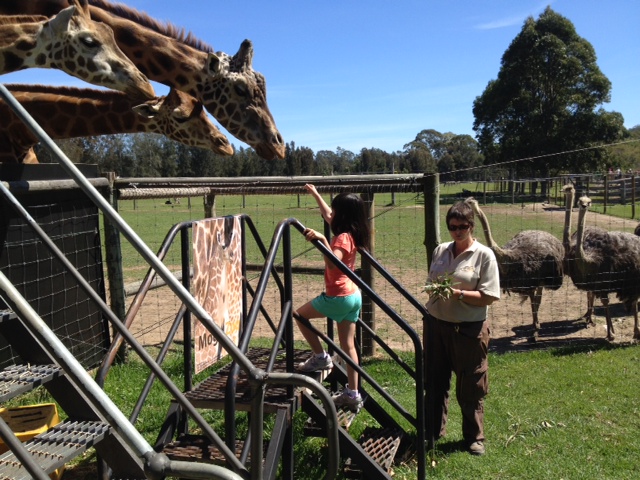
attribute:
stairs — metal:
[190, 340, 406, 472]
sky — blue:
[279, 13, 589, 137]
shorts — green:
[306, 283, 360, 325]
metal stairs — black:
[0, 342, 428, 478]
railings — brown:
[4, 81, 455, 478]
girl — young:
[291, 175, 370, 411]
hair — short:
[445, 196, 478, 233]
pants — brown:
[418, 312, 492, 440]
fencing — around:
[111, 174, 639, 353]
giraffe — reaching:
[7, 81, 244, 159]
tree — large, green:
[469, 5, 633, 202]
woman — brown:
[411, 201, 497, 455]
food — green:
[413, 266, 465, 302]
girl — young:
[288, 185, 378, 406]